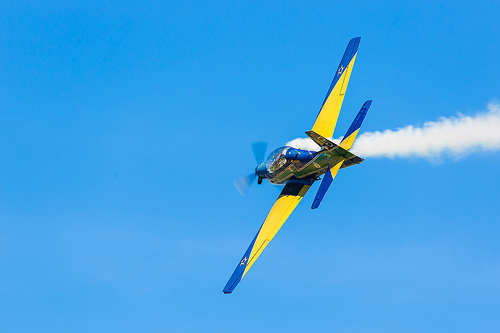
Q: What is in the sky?
A: Plane.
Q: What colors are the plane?
A: Yellow, blue.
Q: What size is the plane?
A: Small.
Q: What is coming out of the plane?
A: Smoke.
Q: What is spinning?
A: Propeller.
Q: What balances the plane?
A: Wings.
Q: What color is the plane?
A: Blue and yellow.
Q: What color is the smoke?
A: White.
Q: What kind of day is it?
A: Clear.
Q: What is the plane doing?
A: Tricks.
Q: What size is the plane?
A: Small.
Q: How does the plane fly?
A: Propeller.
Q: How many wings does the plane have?
A: Two.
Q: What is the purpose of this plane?
A: Stunts.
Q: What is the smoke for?
A: Skywriting.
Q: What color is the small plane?
A: Blue and yellow.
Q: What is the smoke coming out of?
A: The blue and yellow plane.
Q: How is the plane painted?
A: With blue and yellow stripes.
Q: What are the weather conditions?
A: A blue sky.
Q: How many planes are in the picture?
A: One.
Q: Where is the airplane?
A: In the sky.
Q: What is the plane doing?
A: Stunts.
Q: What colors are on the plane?
A: Blue and yellow.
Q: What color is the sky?
A: Blue.